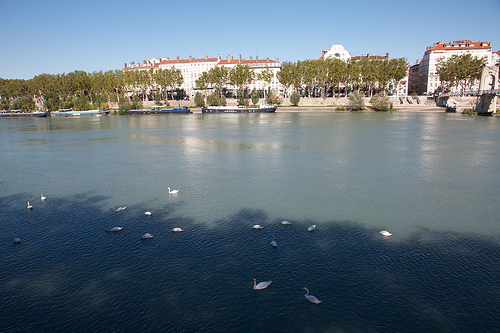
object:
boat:
[0, 110, 48, 119]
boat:
[50, 108, 101, 118]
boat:
[201, 102, 276, 113]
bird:
[251, 225, 266, 230]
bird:
[105, 226, 123, 232]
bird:
[301, 287, 323, 304]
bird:
[140, 233, 153, 240]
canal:
[0, 112, 498, 330]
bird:
[379, 230, 393, 237]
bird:
[166, 187, 179, 195]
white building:
[122, 53, 282, 100]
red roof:
[123, 53, 280, 69]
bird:
[40, 193, 46, 201]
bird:
[111, 206, 127, 213]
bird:
[253, 278, 272, 291]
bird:
[271, 234, 278, 247]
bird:
[308, 225, 316, 232]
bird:
[27, 201, 33, 209]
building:
[424, 40, 492, 54]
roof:
[426, 38, 492, 50]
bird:
[172, 227, 184, 232]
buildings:
[301, 43, 409, 98]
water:
[0, 111, 499, 330]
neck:
[166, 187, 179, 194]